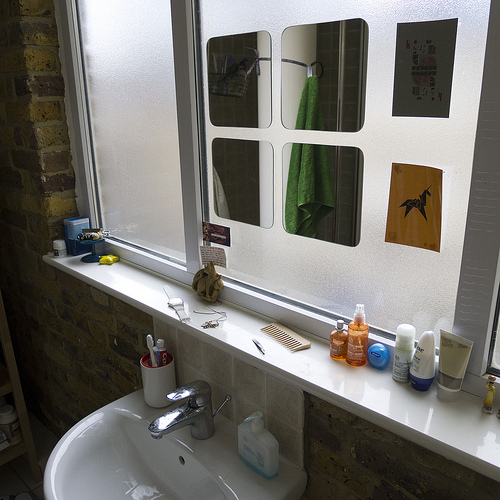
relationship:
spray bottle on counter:
[342, 301, 370, 364] [330, 369, 375, 404]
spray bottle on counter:
[325, 312, 346, 362] [330, 369, 375, 404]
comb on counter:
[259, 322, 313, 352] [46, 248, 498, 479]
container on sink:
[228, 407, 285, 484] [38, 346, 308, 498]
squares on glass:
[234, 50, 380, 242] [220, 0, 274, 32]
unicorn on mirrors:
[396, 180, 434, 220] [204, 15, 369, 249]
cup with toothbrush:
[140, 353, 178, 405] [149, 334, 159, 364]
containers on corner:
[49, 214, 83, 254] [26, 98, 118, 278]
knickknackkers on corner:
[79, 224, 122, 269] [26, 98, 118, 278]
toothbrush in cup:
[141, 330, 156, 367] [140, 353, 178, 405]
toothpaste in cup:
[152, 336, 169, 366] [140, 353, 178, 405]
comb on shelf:
[259, 322, 311, 352] [153, 291, 369, 469]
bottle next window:
[408, 331, 436, 391] [197, 0, 490, 361]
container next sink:
[228, 407, 285, 484] [46, 405, 242, 497]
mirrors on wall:
[204, 15, 369, 249] [1, 17, 498, 371]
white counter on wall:
[131, 251, 391, 416] [1, 17, 498, 371]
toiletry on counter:
[437, 328, 474, 400] [253, 345, 496, 466]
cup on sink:
[140, 353, 178, 405] [38, 380, 310, 499]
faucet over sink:
[137, 367, 249, 495] [35, 387, 333, 496]